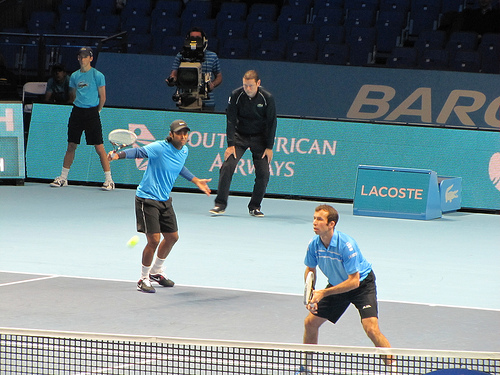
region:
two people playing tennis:
[90, 83, 411, 328]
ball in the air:
[115, 210, 150, 270]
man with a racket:
[286, 196, 388, 321]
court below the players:
[181, 296, 243, 331]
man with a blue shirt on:
[270, 200, 380, 305]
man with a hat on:
[112, 103, 209, 220]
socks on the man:
[131, 255, 178, 285]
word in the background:
[345, 170, 433, 217]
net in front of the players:
[146, 334, 193, 373]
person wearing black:
[222, 68, 298, 156]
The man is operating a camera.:
[160, 23, 226, 115]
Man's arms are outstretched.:
[103, 117, 213, 297]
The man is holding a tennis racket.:
[106, 114, 218, 301]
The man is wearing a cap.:
[104, 117, 213, 294]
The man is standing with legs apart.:
[44, 40, 120, 194]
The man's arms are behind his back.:
[42, 38, 121, 194]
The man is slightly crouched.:
[206, 64, 282, 228]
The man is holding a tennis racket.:
[289, 200, 401, 368]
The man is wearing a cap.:
[47, 36, 117, 193]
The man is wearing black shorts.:
[47, 42, 121, 196]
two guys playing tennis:
[94, 115, 443, 360]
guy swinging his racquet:
[94, 116, 222, 307]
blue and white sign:
[353, 158, 442, 215]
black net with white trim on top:
[56, 317, 291, 372]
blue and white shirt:
[294, 214, 396, 288]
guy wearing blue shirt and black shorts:
[46, 40, 120, 198]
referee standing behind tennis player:
[119, 72, 282, 233]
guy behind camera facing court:
[24, 24, 229, 336]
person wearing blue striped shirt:
[171, 48, 251, 103]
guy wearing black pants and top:
[213, 68, 295, 233]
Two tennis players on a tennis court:
[98, 101, 424, 343]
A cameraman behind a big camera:
[161, 24, 224, 123]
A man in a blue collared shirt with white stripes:
[300, 192, 391, 347]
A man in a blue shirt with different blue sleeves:
[100, 105, 215, 225]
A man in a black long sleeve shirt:
[215, 68, 280, 214]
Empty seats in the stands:
[30, 4, 497, 78]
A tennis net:
[0, 326, 497, 373]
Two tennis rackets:
[93, 121, 378, 316]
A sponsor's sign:
[355, 167, 437, 217]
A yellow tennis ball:
[112, 222, 157, 269]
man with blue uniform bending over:
[301, 201, 398, 367]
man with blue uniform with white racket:
[107, 117, 211, 299]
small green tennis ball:
[127, 230, 141, 252]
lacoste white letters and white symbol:
[357, 180, 459, 210]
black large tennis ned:
[7, 326, 498, 373]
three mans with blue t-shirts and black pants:
[48, 44, 394, 372]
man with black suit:
[211, 68, 279, 217]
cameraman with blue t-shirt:
[165, 23, 221, 111]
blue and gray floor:
[5, 182, 496, 373]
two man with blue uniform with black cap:
[47, 37, 202, 291]